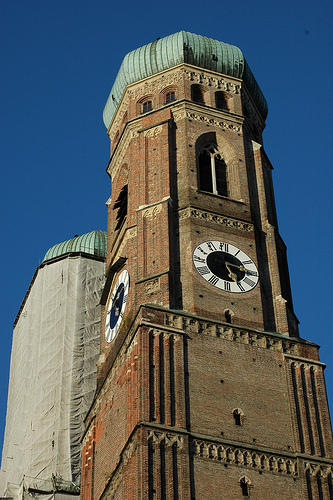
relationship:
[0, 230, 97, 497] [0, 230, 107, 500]
building under building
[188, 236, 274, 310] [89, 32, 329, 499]
clock on tower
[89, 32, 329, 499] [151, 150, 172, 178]
tower made of brick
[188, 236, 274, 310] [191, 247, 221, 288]
clock has roman numerals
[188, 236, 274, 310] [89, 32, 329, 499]
clock on a london tower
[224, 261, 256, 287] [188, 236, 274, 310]
hands of clock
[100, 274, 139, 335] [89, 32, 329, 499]
clock on tower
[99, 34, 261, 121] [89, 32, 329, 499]
roof on tower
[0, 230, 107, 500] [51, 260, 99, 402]
building under cover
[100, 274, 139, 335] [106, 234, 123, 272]
clock on left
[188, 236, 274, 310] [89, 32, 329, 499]
clock on front of tower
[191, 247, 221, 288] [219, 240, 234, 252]
roman numerals number 12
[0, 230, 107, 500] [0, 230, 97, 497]
building on building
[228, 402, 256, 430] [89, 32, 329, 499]
window in tower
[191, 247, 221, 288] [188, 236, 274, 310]
roman numerals on clock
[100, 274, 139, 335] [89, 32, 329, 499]
clock on side of tower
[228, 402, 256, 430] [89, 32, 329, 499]
window on tower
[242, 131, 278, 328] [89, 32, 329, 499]
shadow on tower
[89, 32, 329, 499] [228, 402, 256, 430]
tower has a window